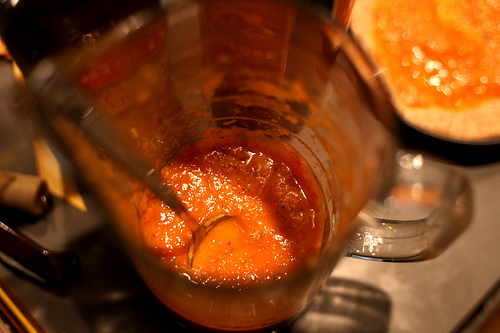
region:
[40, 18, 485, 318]
spoon in thick sauce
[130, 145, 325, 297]
black specks in thick red liquid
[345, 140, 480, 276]
glass handle on side of container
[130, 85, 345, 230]
rings around the glass container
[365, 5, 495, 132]
glistening gooey orange spread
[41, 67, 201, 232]
handle of utensil leaning against container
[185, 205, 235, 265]
curved rim of spoon above liquid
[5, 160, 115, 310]
tan handle on top of black object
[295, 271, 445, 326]
shadow falling on metal surface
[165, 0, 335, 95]
box seen through side of glass container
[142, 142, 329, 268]
Liquid food.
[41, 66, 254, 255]
A spoon to eat the liquid food.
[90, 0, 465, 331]
A glass dish with a handle that is containing the liquid food.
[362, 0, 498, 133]
Food in the background. The origin of the liquid food on the glass container.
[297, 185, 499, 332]
The countertop to place things on.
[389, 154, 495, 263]
Glass handle for the container.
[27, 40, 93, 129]
A spout to pour liquid.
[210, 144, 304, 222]
Small specks of seasoning such as pepper.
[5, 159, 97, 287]
Other objects placed on the counter.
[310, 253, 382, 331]
A shadow cast from the handle.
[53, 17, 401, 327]
a glass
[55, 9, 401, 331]
a glass of liquid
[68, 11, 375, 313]
the liquid is orange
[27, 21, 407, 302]
a spoon is in the glass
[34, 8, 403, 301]
a spoon is in the orange liquid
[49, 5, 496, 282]
the glass has a handle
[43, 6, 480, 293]
orange liquid is at the bottom of the glass mug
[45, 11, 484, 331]
the mug is on a table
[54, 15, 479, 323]
a glass blender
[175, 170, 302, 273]
the soup is red in color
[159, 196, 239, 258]
this is a spoon in the soup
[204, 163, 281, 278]
the soup is delicious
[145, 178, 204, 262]
the spoon is big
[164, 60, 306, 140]
this is a container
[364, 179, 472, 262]
this is a handle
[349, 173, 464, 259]
the handle is glass in nature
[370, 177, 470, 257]
the handle is shiny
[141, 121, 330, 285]
Orange condiment in the glass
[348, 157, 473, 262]
Handle on the side of the glass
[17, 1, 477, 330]
Glass holding the orange condiment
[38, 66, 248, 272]
Silver spoon standing in the glass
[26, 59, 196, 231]
Handle of the spoon standing in the glass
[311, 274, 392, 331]
Shadow of the glass's handle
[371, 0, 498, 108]
Orange condiment spread on food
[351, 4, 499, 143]
Item the orange condiment is spread on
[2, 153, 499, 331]
Dark surface the glass sits on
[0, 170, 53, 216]
Small round light brown handle on the left